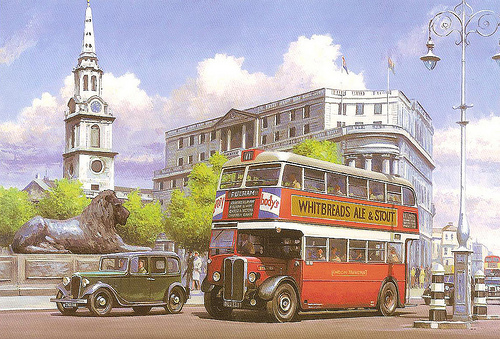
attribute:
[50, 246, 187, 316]
truck — green 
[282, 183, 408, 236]
placard — orange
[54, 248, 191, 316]
green truck — Big 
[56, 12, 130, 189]
tower — clock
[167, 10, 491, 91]
sky —  blue 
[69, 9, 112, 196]
tower — white 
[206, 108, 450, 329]
bus — white 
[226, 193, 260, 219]
placard — destination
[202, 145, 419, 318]
bus — red 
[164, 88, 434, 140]
balcony — building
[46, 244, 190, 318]
car — green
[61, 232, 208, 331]
car — green 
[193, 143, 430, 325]
bus — red 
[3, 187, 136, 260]
lion — statue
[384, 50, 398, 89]
flag — American 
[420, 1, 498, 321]
street lamp — metal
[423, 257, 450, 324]
pylons — black, white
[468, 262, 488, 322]
pylons — black, white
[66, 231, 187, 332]
vehicle — green 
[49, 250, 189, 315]
car — green 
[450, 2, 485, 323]
post — lamp